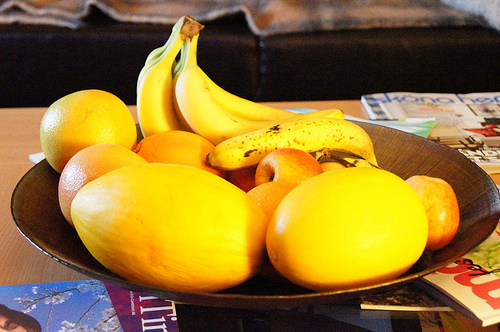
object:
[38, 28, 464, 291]
fruit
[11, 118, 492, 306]
bowl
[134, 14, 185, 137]
bananas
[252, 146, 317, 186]
apple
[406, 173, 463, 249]
apple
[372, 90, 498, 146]
magazines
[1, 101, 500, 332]
table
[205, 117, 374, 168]
banana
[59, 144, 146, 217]
oranges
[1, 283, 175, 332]
magazine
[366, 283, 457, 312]
magazine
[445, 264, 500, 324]
magazine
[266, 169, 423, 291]
mango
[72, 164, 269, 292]
mango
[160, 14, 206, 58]
stem